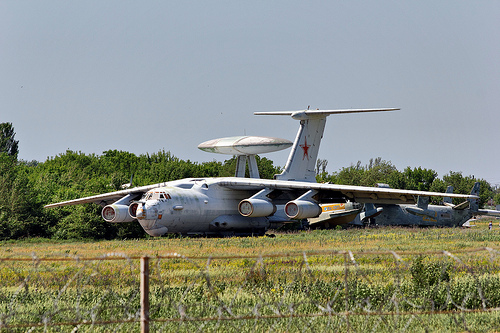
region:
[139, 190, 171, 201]
The cockpit windows.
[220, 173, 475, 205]
The right large side wing.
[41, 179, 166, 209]
The left large side wing.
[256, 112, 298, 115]
The small left wing by the tail.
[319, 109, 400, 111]
The small right wing by the tail.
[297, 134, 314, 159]
The red star on the tail.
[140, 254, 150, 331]
The wooden post on the fence.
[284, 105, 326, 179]
The tail of the plane.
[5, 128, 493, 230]
The trees in the background.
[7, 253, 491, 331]
The barb wire on the fence.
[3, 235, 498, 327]
The grass area where the planes are located.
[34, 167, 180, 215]
The left side wing.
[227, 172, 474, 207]
The right side wing.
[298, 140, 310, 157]
The star on the tail.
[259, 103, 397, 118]
The wings of the tail.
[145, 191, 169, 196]
The windows of the cockpit area.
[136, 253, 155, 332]
The wooden post of the fence.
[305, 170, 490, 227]
The smaller planes behind the jet.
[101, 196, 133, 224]
a white engine on a plane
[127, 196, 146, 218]
a white engine on a plane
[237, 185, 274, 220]
a white engine on a plane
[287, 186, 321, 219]
a white engine on a plane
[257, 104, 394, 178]
the tail of a plane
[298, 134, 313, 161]
a red star on the plane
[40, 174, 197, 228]
the wing of a plane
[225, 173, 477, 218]
the wing of a plane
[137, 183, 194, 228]
the nose of a plane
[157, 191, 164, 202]
the window of a plane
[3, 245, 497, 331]
a barb wire fence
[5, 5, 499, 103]
a cloudless sky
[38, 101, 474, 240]
a large airplane on the ground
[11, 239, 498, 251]
a grassy open field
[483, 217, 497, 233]
a person is standing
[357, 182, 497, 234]
an airplane sits on the ground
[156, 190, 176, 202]
three airplane windows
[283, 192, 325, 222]
an engine to an airplane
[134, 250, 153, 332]
a pole support for a fence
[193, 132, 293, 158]
An ecom comm tower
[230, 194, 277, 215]
A planes jet engine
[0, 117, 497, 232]
A green tree line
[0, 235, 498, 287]
a green grassy field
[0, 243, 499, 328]
A barbed wire fence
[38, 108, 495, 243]
Many grey planes on field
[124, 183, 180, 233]
Nose of jet plane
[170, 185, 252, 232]
Fuselage of a plane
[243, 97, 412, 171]
Tail end of plane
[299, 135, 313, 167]
Red star painted on